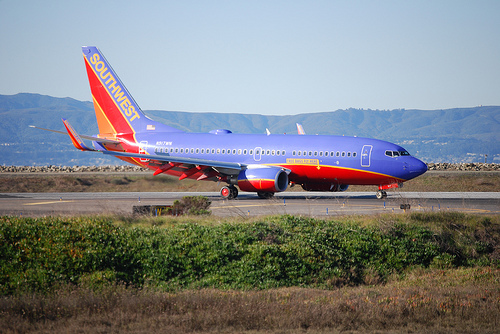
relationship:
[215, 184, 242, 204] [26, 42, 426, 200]
wheel of plane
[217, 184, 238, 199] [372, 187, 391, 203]
wheel of plane wheels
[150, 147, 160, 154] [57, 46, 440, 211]
plane window on plane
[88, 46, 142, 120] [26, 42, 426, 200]
airplane name on plane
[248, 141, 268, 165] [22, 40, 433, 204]
door on airplane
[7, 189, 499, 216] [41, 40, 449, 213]
airplane runway under airplane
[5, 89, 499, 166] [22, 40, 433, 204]
hills behind behind airplane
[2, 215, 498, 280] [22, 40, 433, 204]
front bushes in front of airplane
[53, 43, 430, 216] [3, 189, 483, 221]
airplane on ground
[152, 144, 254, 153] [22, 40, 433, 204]
row of windows on airplane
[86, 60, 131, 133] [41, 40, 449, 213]
red paint on airplane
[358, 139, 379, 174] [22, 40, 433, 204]
airplane door of airplane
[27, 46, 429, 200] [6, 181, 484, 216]
an airplane on landing strip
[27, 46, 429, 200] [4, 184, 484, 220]
an airplane in landing strip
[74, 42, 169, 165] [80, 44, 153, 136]
stripes on tail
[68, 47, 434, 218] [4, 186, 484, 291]
an airplane on ground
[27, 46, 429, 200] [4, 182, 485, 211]
an airplane on runway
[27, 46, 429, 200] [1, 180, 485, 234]
an airplane on runway